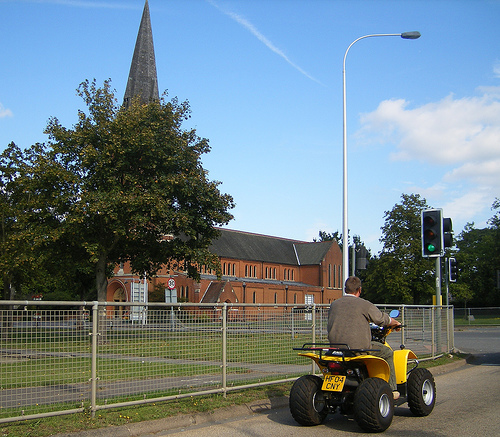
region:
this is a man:
[323, 262, 390, 350]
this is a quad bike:
[320, 351, 421, 416]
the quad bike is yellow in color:
[322, 344, 412, 378]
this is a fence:
[182, 302, 248, 384]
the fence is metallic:
[129, 310, 238, 398]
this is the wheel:
[353, 380, 395, 425]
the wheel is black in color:
[357, 377, 399, 426]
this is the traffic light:
[422, 206, 449, 256]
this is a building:
[242, 237, 311, 294]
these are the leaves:
[78, 127, 213, 234]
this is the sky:
[203, 34, 276, 154]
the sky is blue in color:
[234, 68, 297, 163]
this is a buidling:
[219, 223, 326, 280]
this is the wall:
[251, 267, 289, 300]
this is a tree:
[54, 127, 156, 250]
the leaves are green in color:
[108, 140, 163, 193]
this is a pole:
[336, 76, 354, 248]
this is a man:
[324, 282, 375, 350]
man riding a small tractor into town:
[289, 277, 434, 429]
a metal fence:
[1, 304, 453, 421]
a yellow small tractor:
[292, 309, 436, 430]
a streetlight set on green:
[423, 207, 440, 254]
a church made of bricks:
[106, 224, 345, 324]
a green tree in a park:
[3, 78, 235, 340]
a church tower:
[123, 2, 162, 109]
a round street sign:
[166, 278, 178, 290]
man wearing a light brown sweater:
[328, 294, 388, 351]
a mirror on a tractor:
[388, 308, 400, 320]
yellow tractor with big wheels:
[296, 349, 436, 413]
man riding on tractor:
[281, 285, 418, 435]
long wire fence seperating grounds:
[7, 310, 289, 405]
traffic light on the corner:
[408, 210, 448, 267]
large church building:
[110, 239, 327, 319]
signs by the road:
[163, 278, 184, 330]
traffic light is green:
[413, 209, 441, 269]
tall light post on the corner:
[318, 4, 419, 299]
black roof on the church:
[221, 227, 324, 273]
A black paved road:
[99, 301, 496, 428]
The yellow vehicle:
[286, 332, 458, 428]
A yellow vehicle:
[280, 330, 440, 434]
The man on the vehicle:
[314, 269, 424, 396]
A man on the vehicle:
[319, 278, 414, 372]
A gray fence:
[1, 280, 452, 414]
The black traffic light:
[407, 198, 450, 262]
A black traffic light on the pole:
[409, 200, 452, 267]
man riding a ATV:
[278, 263, 432, 433]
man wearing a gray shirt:
[319, 297, 379, 352]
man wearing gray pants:
[366, 337, 401, 390]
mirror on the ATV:
[385, 305, 402, 320]